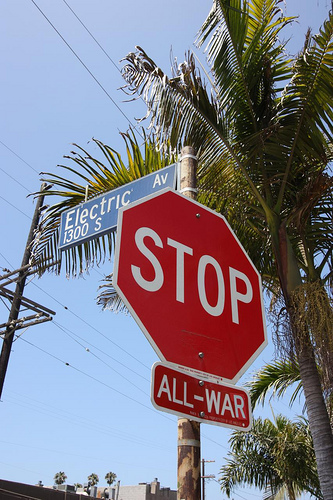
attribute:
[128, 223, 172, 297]
s — white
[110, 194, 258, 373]
sign — stop, octagon, identification, red, white, hexigonal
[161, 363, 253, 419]
sign — all-war, altered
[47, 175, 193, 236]
sign — blue, electric ave 1300s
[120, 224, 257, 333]
stop — word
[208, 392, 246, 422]
war — word, white, letters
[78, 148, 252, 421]
signs — attached, red, hanging on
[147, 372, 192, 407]
all — white, letters, word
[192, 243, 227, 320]
o — letter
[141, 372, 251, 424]
message — liberal, pacifist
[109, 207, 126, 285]
border — light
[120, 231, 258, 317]
lettering — white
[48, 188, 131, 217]
electric — word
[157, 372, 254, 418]
all war — text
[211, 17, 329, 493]
trees — palm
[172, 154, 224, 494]
sign post — metal, rusty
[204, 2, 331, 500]
tree — palm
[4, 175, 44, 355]
post — electric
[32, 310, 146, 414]
cables — electric, hanging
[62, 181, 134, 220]
name — electric avenue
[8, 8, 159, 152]
sky — blue, sunny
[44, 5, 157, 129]
wires — black, electric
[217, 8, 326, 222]
leaves — green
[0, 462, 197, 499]
buildings — assorted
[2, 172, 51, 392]
pole — power